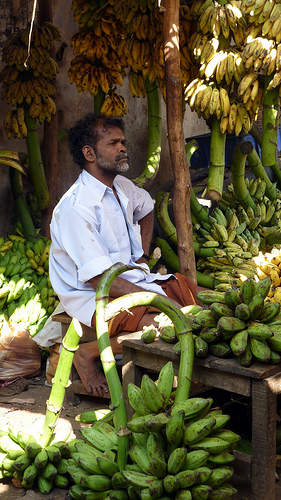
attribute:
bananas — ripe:
[184, 2, 279, 137]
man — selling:
[47, 111, 201, 335]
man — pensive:
[47, 111, 181, 330]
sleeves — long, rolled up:
[58, 214, 123, 283]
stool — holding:
[53, 308, 136, 379]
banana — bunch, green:
[209, 40, 235, 78]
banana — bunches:
[0, 2, 280, 227]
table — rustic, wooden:
[116, 329, 280, 499]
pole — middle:
[160, 0, 199, 301]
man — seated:
[53, 110, 152, 273]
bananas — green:
[173, 13, 280, 120]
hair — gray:
[77, 92, 119, 157]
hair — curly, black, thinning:
[67, 106, 129, 167]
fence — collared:
[44, 176, 159, 282]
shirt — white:
[63, 186, 135, 263]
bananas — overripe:
[76, 61, 112, 94]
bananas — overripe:
[121, 43, 161, 71]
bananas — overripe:
[73, 34, 110, 58]